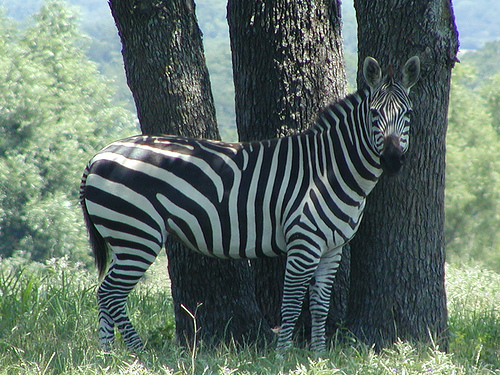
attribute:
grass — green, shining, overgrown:
[2, 275, 499, 374]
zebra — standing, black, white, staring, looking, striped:
[70, 53, 431, 362]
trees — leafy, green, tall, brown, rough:
[3, 1, 500, 287]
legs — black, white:
[78, 236, 349, 354]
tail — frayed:
[68, 162, 122, 282]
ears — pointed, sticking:
[357, 51, 423, 90]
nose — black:
[373, 142, 409, 177]